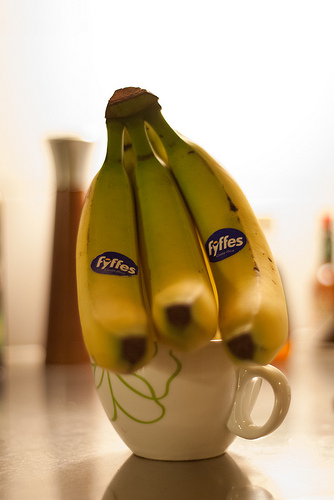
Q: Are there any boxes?
A: No, there are no boxes.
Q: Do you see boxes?
A: No, there are no boxes.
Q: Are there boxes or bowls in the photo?
A: No, there are no boxes or bowls.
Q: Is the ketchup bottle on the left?
A: Yes, the ketchup bottle is on the left of the image.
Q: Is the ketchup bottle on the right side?
A: No, the ketchup bottle is on the left of the image.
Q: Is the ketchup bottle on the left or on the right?
A: The ketchup bottle is on the left of the image.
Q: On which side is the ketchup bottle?
A: The ketchup bottle is on the left of the image.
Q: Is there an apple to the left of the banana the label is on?
A: No, there is a ketchup bottle to the left of the banana.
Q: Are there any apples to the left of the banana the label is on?
A: No, there is a ketchup bottle to the left of the banana.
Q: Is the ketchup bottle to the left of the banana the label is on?
A: Yes, the ketchup bottle is to the left of the banana.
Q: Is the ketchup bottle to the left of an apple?
A: No, the ketchup bottle is to the left of the banana.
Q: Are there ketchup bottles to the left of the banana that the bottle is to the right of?
A: Yes, there is a ketchup bottle to the left of the banana.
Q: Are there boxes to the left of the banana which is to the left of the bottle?
A: No, there is a ketchup bottle to the left of the banana.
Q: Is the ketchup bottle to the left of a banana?
A: Yes, the ketchup bottle is to the left of a banana.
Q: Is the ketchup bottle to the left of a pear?
A: No, the ketchup bottle is to the left of a banana.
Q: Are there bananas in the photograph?
A: Yes, there is a banana.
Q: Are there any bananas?
A: Yes, there is a banana.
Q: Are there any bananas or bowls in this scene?
A: Yes, there is a banana.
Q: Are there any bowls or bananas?
A: Yes, there is a banana.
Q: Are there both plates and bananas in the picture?
A: No, there is a banana but no plates.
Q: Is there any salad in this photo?
A: No, there is no salad.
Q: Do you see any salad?
A: No, there is no salad.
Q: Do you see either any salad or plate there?
A: No, there are no salad or plates.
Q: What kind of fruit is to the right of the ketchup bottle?
A: The fruit is a banana.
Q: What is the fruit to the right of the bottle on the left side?
A: The fruit is a banana.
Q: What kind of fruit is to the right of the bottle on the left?
A: The fruit is a banana.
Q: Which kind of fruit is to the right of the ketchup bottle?
A: The fruit is a banana.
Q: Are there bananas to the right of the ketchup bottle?
A: Yes, there is a banana to the right of the ketchup bottle.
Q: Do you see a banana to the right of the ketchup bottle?
A: Yes, there is a banana to the right of the ketchup bottle.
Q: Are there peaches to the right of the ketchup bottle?
A: No, there is a banana to the right of the ketchup bottle.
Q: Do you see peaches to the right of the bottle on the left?
A: No, there is a banana to the right of the ketchup bottle.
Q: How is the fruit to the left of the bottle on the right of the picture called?
A: The fruit is a banana.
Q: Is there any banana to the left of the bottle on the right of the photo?
A: Yes, there is a banana to the left of the bottle.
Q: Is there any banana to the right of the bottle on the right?
A: No, the banana is to the left of the bottle.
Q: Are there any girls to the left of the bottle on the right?
A: No, there is a banana to the left of the bottle.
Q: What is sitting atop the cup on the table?
A: The banana is sitting atop the cup.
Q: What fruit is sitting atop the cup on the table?
A: The fruit is a banana.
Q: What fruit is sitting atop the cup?
A: The fruit is a banana.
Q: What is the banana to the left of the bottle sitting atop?
A: The banana is sitting atop the cup.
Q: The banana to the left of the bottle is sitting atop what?
A: The banana is sitting atop the cup.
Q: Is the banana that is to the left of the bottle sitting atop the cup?
A: Yes, the banana is sitting atop the cup.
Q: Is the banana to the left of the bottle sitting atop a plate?
A: No, the banana is sitting atop the cup.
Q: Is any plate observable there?
A: No, there are no plates.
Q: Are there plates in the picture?
A: No, there are no plates.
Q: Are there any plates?
A: No, there are no plates.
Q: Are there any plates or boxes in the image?
A: No, there are no plates or boxes.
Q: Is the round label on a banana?
A: Yes, the label is on a banana.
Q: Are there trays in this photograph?
A: No, there are no trays.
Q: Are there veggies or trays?
A: No, there are no trays or veggies.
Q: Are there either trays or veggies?
A: No, there are no trays or veggies.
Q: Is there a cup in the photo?
A: Yes, there is a cup.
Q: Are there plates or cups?
A: Yes, there is a cup.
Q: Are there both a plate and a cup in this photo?
A: No, there is a cup but no plates.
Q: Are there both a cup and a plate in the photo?
A: No, there is a cup but no plates.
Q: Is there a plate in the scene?
A: No, there are no plates.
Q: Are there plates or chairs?
A: No, there are no plates or chairs.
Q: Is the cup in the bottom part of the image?
A: Yes, the cup is in the bottom of the image.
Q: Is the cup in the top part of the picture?
A: No, the cup is in the bottom of the image.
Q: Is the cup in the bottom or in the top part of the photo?
A: The cup is in the bottom of the image.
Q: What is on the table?
A: The cup is on the table.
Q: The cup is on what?
A: The cup is on the table.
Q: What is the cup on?
A: The cup is on the table.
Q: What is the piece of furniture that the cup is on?
A: The piece of furniture is a table.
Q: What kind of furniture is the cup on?
A: The cup is on the table.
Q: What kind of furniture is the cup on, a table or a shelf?
A: The cup is on a table.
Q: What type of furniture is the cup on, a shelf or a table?
A: The cup is on a table.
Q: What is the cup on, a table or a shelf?
A: The cup is on a table.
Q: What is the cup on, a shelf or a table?
A: The cup is on a table.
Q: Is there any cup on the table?
A: Yes, there is a cup on the table.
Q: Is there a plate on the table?
A: No, there is a cup on the table.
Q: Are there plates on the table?
A: No, there is a cup on the table.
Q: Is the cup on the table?
A: Yes, the cup is on the table.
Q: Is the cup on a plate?
A: No, the cup is on the table.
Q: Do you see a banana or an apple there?
A: Yes, there is a banana.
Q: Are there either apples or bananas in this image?
A: Yes, there is a banana.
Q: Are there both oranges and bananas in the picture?
A: No, there is a banana but no oranges.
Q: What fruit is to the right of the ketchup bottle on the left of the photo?
A: The fruit is a banana.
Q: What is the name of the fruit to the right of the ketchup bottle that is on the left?
A: The fruit is a banana.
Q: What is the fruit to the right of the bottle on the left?
A: The fruit is a banana.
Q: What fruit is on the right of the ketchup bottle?
A: The fruit is a banana.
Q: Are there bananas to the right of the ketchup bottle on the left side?
A: Yes, there is a banana to the right of the ketchup bottle.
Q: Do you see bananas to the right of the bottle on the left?
A: Yes, there is a banana to the right of the ketchup bottle.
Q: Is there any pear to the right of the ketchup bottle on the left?
A: No, there is a banana to the right of the ketchup bottle.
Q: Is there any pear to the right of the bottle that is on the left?
A: No, there is a banana to the right of the ketchup bottle.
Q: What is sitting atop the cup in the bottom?
A: The banana is sitting atop the cup.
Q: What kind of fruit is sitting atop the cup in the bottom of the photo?
A: The fruit is a banana.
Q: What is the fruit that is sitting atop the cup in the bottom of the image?
A: The fruit is a banana.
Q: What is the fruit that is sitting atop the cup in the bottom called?
A: The fruit is a banana.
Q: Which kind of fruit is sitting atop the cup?
A: The fruit is a banana.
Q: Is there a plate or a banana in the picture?
A: Yes, there is a banana.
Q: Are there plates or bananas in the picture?
A: Yes, there is a banana.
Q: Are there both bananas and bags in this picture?
A: No, there is a banana but no bags.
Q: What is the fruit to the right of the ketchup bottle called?
A: The fruit is a banana.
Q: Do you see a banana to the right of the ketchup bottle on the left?
A: Yes, there is a banana to the right of the ketchup bottle.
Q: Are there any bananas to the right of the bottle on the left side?
A: Yes, there is a banana to the right of the ketchup bottle.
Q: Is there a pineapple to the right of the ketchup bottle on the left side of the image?
A: No, there is a banana to the right of the ketchup bottle.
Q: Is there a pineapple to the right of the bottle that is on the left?
A: No, there is a banana to the right of the ketchup bottle.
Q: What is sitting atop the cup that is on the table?
A: The banana is sitting atop the cup.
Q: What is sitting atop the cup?
A: The banana is sitting atop the cup.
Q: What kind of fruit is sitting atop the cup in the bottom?
A: The fruit is a banana.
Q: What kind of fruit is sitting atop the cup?
A: The fruit is a banana.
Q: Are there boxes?
A: No, there are no boxes.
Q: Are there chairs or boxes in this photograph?
A: No, there are no boxes or chairs.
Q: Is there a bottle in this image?
A: Yes, there is a bottle.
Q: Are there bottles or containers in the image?
A: Yes, there is a bottle.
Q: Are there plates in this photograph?
A: No, there are no plates.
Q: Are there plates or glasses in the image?
A: No, there are no plates or glasses.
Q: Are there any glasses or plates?
A: No, there are no plates or glasses.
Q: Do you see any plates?
A: No, there are no plates.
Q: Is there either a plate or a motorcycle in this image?
A: No, there are no plates or motorcycles.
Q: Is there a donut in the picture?
A: Yes, there are donuts.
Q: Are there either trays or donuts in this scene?
A: Yes, there are donuts.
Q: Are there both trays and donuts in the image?
A: No, there are donuts but no trays.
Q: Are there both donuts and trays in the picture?
A: No, there are donuts but no trays.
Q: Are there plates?
A: No, there are no plates.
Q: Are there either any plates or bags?
A: No, there are no plates or bags.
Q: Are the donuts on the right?
A: Yes, the donuts are on the right of the image.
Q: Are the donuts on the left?
A: No, the donuts are on the right of the image.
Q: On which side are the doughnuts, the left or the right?
A: The doughnuts are on the right of the image.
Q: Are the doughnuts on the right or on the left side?
A: The doughnuts are on the right of the image.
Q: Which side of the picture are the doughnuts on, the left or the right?
A: The doughnuts are on the right of the image.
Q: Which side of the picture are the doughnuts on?
A: The doughnuts are on the right of the image.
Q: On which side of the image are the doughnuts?
A: The doughnuts are on the right of the image.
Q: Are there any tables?
A: Yes, there is a table.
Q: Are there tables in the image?
A: Yes, there is a table.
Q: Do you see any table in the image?
A: Yes, there is a table.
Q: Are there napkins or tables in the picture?
A: Yes, there is a table.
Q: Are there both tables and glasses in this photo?
A: No, there is a table but no glasses.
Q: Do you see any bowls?
A: No, there are no bowls.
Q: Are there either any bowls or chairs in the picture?
A: No, there are no bowls or chairs.